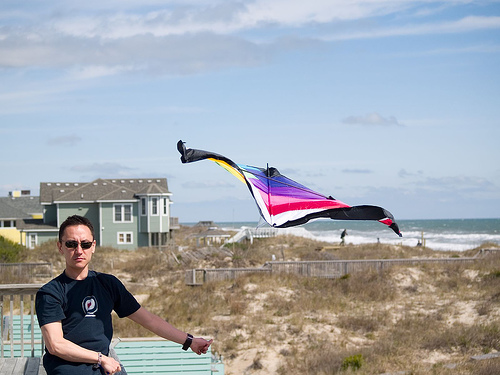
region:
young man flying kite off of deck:
[33, 141, 402, 374]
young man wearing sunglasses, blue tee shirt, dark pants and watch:
[33, 215, 211, 372]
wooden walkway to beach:
[2, 259, 495, 292]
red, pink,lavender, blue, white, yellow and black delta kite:
[177, 140, 404, 238]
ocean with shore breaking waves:
[176, 217, 498, 249]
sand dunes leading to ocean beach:
[5, 227, 498, 374]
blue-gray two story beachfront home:
[0, 179, 173, 252]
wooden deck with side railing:
[1, 283, 226, 373]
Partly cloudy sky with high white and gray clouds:
[3, 1, 497, 218]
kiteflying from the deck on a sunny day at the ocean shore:
[0, 0, 497, 374]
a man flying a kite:
[8, 173, 435, 373]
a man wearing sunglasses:
[51, 199, 120, 276]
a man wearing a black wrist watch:
[183, 321, 199, 359]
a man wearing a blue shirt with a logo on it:
[42, 211, 130, 343]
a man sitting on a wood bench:
[11, 265, 151, 372]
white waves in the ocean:
[387, 221, 487, 272]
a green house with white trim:
[103, 170, 177, 242]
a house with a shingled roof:
[99, 177, 168, 223]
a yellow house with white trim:
[0, 191, 30, 246]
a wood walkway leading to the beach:
[199, 242, 496, 300]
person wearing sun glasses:
[27, 203, 232, 372]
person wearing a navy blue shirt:
[22, 214, 223, 372]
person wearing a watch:
[23, 210, 223, 372]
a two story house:
[0, 173, 175, 262]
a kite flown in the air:
[170, 131, 416, 257]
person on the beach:
[337, 227, 349, 249]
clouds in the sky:
[12, 3, 437, 92]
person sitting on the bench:
[23, 212, 228, 372]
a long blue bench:
[35, 339, 224, 371]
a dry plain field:
[236, 280, 497, 367]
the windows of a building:
[109, 200, 136, 226]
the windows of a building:
[113, 227, 134, 243]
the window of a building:
[146, 192, 157, 217]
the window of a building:
[135, 195, 145, 215]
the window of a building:
[160, 192, 167, 217]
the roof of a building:
[39, 175, 137, 205]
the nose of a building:
[72, 242, 85, 258]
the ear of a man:
[89, 235, 98, 257]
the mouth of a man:
[69, 253, 86, 264]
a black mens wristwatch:
[180, 334, 194, 351]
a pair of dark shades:
[57, 237, 96, 249]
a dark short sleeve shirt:
[36, 273, 141, 370]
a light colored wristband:
[93, 352, 105, 369]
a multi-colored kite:
[172, 140, 403, 243]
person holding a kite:
[37, 137, 404, 373]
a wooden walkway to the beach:
[171, 255, 496, 279]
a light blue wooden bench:
[4, 328, 221, 371]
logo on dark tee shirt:
[80, 296, 100, 316]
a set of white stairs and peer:
[221, 223, 281, 245]